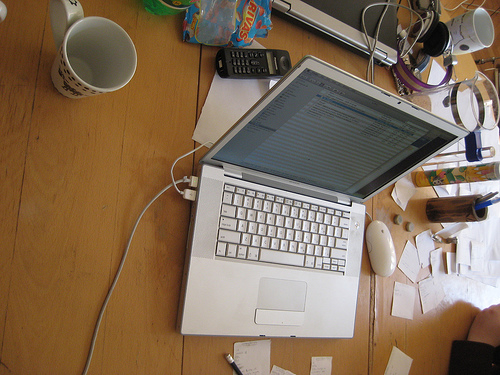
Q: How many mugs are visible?
A: 2.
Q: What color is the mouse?
A: White.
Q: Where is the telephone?
A: Between the computers.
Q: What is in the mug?
A: Nothing.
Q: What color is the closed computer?
A: Black and silver.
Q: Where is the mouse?
A: Right of computer.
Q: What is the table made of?
A: Wood.